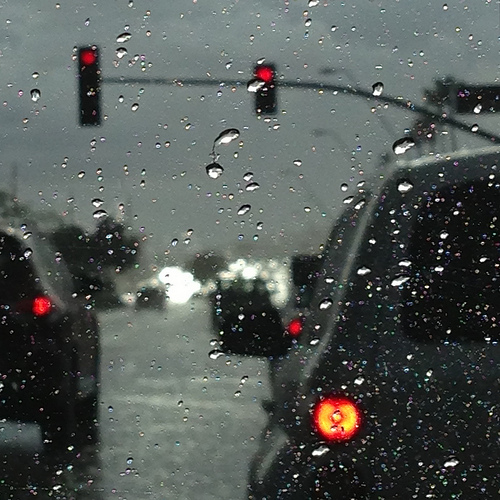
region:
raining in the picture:
[150, 377, 239, 486]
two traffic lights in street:
[66, 33, 391, 178]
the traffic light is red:
[203, 35, 380, 142]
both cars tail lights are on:
[270, 301, 332, 488]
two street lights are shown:
[268, 45, 418, 167]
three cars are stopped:
[14, 271, 432, 483]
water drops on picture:
[191, 162, 416, 410]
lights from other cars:
[157, 261, 216, 343]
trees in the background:
[58, 215, 201, 304]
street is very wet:
[136, 409, 191, 482]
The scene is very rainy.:
[2, 2, 498, 498]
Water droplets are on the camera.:
[90, 97, 320, 257]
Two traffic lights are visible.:
[56, 32, 307, 144]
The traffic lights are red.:
[51, 34, 296, 142]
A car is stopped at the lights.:
[199, 123, 498, 498]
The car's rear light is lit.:
[296, 386, 373, 453]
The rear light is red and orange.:
[298, 389, 375, 449]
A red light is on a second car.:
[25, 287, 57, 318]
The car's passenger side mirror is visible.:
[198, 267, 297, 370]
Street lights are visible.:
[263, 57, 403, 271]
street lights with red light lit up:
[27, 15, 326, 172]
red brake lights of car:
[294, 378, 389, 473]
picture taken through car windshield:
[40, 102, 489, 476]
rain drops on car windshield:
[180, 117, 270, 214]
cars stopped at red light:
[20, 130, 487, 491]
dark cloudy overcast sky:
[135, 16, 398, 48]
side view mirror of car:
[193, 261, 297, 369]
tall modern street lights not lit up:
[290, 43, 392, 237]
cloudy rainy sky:
[76, 125, 234, 207]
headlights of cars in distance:
[158, 253, 318, 308]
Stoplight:
[77, 45, 102, 122]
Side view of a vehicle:
[211, 135, 496, 497]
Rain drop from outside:
[207, 128, 237, 178]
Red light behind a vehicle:
[315, 395, 360, 442]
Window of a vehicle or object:
[2, 4, 494, 495]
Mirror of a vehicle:
[212, 287, 289, 354]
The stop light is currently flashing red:
[72, 45, 104, 129]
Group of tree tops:
[404, 68, 464, 142]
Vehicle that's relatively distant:
[128, 287, 166, 311]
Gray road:
[98, 297, 263, 498]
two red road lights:
[24, 38, 329, 188]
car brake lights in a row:
[195, 163, 499, 454]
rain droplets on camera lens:
[190, 101, 290, 265]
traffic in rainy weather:
[30, 34, 452, 459]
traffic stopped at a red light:
[15, 32, 396, 386]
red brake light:
[314, 392, 364, 446]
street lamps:
[234, 47, 438, 242]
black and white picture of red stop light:
[25, 37, 482, 204]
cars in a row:
[248, 144, 486, 496]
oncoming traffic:
[158, 207, 300, 372]